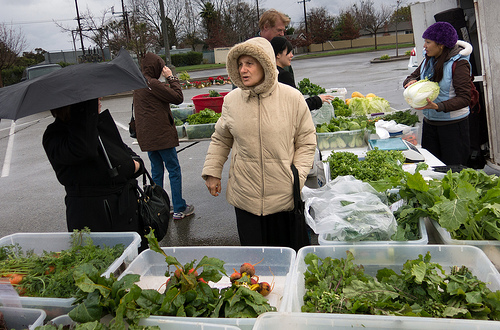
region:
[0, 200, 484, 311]
plastic bins full of vegetables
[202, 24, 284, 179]
a woman wearing a coat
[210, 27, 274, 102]
a woman wearing a hood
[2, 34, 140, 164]
a woman holding a umbrella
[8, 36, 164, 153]
a woman standing under a umbrella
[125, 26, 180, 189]
a woman wearing a brown coat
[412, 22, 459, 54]
a woman wearing a purple hat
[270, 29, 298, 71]
a woman with black hair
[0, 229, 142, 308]
a plastic container of carrots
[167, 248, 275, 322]
a plastic bin full of radish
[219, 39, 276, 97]
fur around the hood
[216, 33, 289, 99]
the hood of the jacket is up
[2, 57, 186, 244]
woman holding an umbrella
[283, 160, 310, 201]
hand is in the pocket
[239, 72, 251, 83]
mouth is slightly open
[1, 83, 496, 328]
various fruits and vegetables on display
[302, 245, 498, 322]
green leaves in a clear plastic bin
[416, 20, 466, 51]
purple cap on the head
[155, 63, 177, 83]
hand raised to the head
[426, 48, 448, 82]
dark hair laying over the shoulder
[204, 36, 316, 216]
the woman is wearing a coat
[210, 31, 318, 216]
the coat is tan in color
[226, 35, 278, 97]
the coat has a hood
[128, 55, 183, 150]
the woman is wearing a coat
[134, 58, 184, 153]
the coat is brown in color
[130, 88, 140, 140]
the woman is carrying a bad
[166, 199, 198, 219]
the woman is wearing sneakers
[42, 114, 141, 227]
the woman is wearing a coat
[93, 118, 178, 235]
the woman is carrying a purse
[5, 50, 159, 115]
the woman is carrying an umbrella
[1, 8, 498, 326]
People at an outdoor vegetable stand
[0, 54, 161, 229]
Woman holding an umbrella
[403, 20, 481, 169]
Woman talking to customers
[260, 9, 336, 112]
Man and woman talking to vendor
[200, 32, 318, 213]
Woman wearing a winter jacket with hood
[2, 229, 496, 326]
Vegetables in plastic bins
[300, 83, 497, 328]
Vegetables in plastic bins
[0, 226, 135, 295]
Carrots in a plastic bin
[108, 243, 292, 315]
Radishes in a plastic bin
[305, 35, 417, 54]
Wooden fence in front of house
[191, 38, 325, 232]
a woman wearing a tan jacket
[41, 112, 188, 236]
a woman wearing a black jacket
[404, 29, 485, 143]
a woman wearing a blue jacket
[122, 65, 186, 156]
a woman wearing a brown jacket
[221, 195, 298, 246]
a woman wearing black pants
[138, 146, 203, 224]
a woman wearing some blue jeans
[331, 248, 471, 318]
a bucket of plant leaves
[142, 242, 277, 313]
a bucket of plants with fruits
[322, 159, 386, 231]
a bunch of clear bags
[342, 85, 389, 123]
a bunch of cabbages